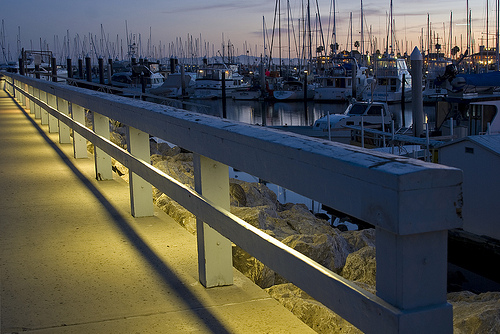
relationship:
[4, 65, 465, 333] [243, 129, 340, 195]
guard rail made of wood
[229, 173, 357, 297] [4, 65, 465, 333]
rocks are behind guard rail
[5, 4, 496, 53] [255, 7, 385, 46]
sky has clouds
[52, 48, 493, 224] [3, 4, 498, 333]
boats are in picture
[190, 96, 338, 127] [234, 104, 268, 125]
water reflecting light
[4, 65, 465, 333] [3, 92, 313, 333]
guard rail along sidewalk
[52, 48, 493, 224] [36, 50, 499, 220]
boats are in bay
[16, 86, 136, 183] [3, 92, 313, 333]
lighting along sidewalk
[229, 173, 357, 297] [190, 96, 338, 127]
rocks are by water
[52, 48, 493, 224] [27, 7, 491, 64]
boats have masts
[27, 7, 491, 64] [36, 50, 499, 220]
masts are in bay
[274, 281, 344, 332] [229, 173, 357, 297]
green growth on rocks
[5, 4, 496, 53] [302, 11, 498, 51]
sky at sunset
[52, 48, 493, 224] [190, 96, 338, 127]
boats are in water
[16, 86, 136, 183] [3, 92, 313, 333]
lighting on sidewalk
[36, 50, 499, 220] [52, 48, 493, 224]
bay for boats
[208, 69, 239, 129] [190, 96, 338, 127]
pole in water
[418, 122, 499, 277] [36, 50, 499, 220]
house in bay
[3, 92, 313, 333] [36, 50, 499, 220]
sidewalk of bay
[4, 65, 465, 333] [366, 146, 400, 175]
guard rail has chipped paint